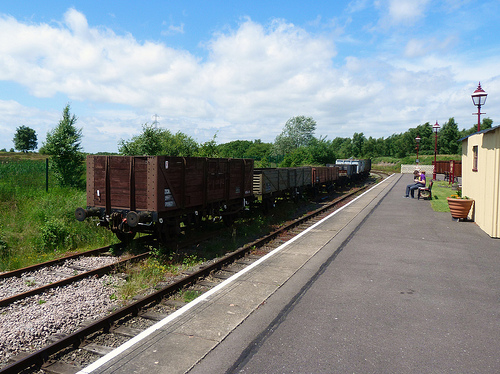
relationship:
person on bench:
[410, 171, 427, 197] [416, 170, 433, 200]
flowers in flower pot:
[448, 192, 470, 199] [448, 197, 473, 218]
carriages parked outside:
[74, 154, 372, 241] [6, 2, 492, 372]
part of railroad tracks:
[59, 258, 101, 298] [21, 262, 101, 338]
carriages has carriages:
[74, 154, 372, 241] [86, 153, 337, 222]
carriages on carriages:
[74, 154, 372, 241] [74, 154, 372, 241]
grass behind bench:
[424, 179, 461, 211] [417, 178, 433, 197]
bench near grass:
[417, 180, 434, 200] [424, 170, 462, 212]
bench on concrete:
[394, 173, 449, 206] [76, 172, 495, 374]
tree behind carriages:
[37, 102, 85, 186] [74, 154, 372, 241]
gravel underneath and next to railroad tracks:
[0, 250, 124, 360] [0, 234, 160, 374]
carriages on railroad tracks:
[74, 154, 372, 241] [0, 234, 160, 374]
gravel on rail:
[4, 243, 137, 359] [0, 170, 370, 371]